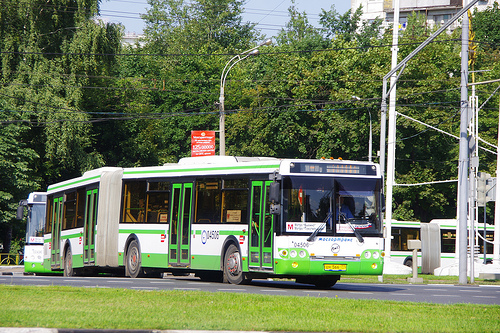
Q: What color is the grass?
A: Green.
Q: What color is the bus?
A: Green and white.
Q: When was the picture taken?
A: Daytime.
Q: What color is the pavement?
A: Gray.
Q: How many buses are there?
A: Two.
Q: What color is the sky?
A: Blue.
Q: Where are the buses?
A: On the street.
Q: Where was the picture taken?
A: On a public street.